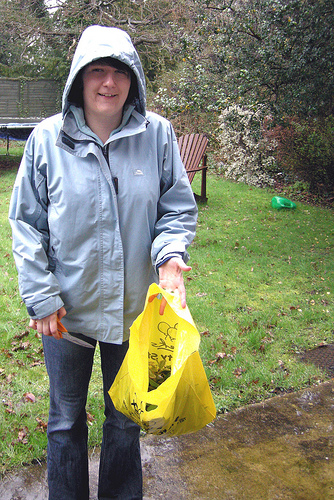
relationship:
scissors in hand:
[56, 320, 94, 349] [29, 307, 65, 338]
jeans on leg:
[40, 329, 143, 498] [40, 323, 143, 498]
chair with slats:
[176, 133, 207, 208] [177, 131, 208, 183]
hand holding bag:
[152, 250, 194, 312] [113, 290, 217, 443]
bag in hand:
[106, 281, 218, 437] [146, 253, 192, 315]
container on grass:
[264, 194, 296, 218] [0, 136, 332, 473]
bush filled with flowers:
[214, 101, 282, 197] [208, 102, 285, 181]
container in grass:
[264, 194, 296, 218] [245, 237, 289, 282]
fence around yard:
[0, 67, 58, 130] [200, 131, 300, 239]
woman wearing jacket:
[8, 23, 197, 498] [6, 23, 198, 344]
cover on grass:
[266, 190, 299, 210] [4, 137, 331, 313]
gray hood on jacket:
[59, 23, 152, 130] [7, 108, 198, 345]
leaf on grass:
[209, 343, 216, 351] [0, 136, 332, 473]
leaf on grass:
[215, 352, 222, 358] [0, 136, 332, 473]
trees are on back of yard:
[146, 34, 332, 279] [0, 142, 324, 466]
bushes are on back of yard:
[189, 100, 272, 200] [0, 142, 324, 466]